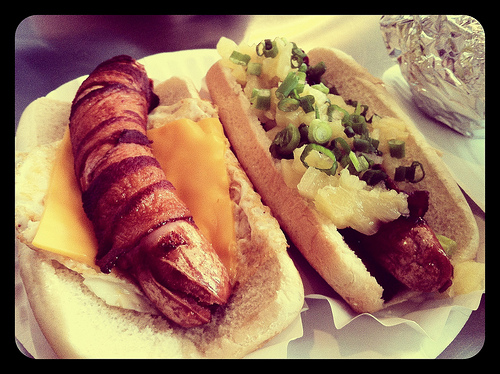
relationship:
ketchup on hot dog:
[374, 212, 455, 290] [205, 34, 483, 316]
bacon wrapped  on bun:
[66, 56, 230, 330] [208, 101, 303, 301]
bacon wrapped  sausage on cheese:
[66, 56, 230, 330] [28, 114, 238, 281]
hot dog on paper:
[205, 34, 483, 316] [246, 274, 485, 366]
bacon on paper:
[66, 56, 230, 330] [246, 274, 485, 366]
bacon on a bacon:
[59, 101, 164, 258] [66, 56, 230, 330]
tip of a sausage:
[378, 209, 455, 294] [68, 54, 231, 327]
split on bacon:
[148, 255, 226, 325] [66, 56, 230, 330]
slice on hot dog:
[328, 96, 391, 145] [207, 46, 451, 281]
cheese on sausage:
[28, 114, 238, 281] [68, 54, 231, 327]